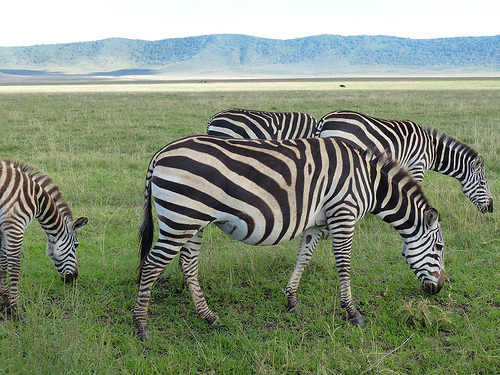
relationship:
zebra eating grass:
[129, 135, 446, 339] [2, 90, 499, 373]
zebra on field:
[208, 108, 318, 139] [4, 86, 494, 373]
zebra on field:
[320, 101, 490, 203] [4, 86, 494, 373]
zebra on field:
[129, 135, 446, 339] [4, 86, 494, 373]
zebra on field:
[0, 153, 87, 320] [4, 86, 494, 373]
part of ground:
[246, 271, 270, 300] [209, 247, 292, 290]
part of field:
[254, 263, 275, 290] [4, 86, 494, 373]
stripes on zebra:
[202, 153, 320, 240] [115, 125, 405, 305]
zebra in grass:
[129, 135, 446, 339] [2, 90, 499, 373]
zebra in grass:
[320, 101, 490, 203] [2, 90, 499, 373]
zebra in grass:
[208, 108, 318, 139] [2, 90, 499, 373]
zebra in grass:
[0, 153, 87, 320] [2, 90, 499, 373]